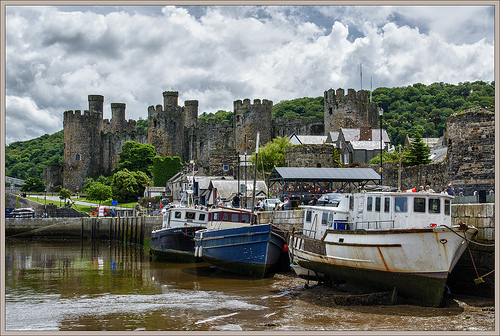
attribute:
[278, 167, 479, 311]
boat — aground, rusty, white, black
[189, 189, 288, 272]
boat — blue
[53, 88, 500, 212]
castle — rustic, old, stone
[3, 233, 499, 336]
water — dingy, brown, shallow, dirty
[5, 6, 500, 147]
sky — cloudy, stormy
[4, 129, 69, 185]
hillside — tree covered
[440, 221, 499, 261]
rope — black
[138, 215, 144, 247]
post — wooden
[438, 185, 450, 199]
tourist — standing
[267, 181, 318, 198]
streamer — colorful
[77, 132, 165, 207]
foliage — abundant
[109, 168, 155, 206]
tree — green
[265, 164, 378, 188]
roof — blue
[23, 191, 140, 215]
road — paved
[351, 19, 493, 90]
cloud — white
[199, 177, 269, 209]
building — small